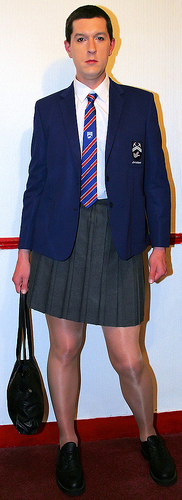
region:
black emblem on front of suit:
[130, 139, 144, 160]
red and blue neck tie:
[81, 94, 98, 206]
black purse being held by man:
[3, 284, 49, 434]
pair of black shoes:
[51, 430, 179, 492]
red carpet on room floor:
[88, 422, 138, 499]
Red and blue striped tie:
[82, 94, 96, 207]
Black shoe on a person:
[142, 433, 174, 484]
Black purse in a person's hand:
[5, 301, 48, 435]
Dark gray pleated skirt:
[24, 198, 145, 325]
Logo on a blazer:
[129, 141, 143, 165]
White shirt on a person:
[72, 74, 107, 198]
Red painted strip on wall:
[0, 236, 18, 246]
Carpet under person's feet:
[3, 434, 178, 497]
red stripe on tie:
[86, 94, 94, 99]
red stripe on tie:
[83, 115, 96, 132]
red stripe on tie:
[81, 137, 95, 158]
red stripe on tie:
[81, 148, 96, 167]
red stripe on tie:
[80, 160, 97, 178]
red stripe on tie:
[81, 172, 96, 188]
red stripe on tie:
[78, 182, 96, 202]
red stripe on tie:
[85, 194, 96, 208]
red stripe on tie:
[86, 101, 91, 108]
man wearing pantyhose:
[10, 9, 172, 494]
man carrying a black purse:
[6, 5, 180, 488]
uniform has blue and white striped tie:
[17, 61, 171, 313]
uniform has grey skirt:
[17, 178, 180, 345]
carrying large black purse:
[0, 289, 79, 441]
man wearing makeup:
[45, 3, 141, 83]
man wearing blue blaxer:
[6, 56, 171, 284]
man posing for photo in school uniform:
[8, 8, 179, 474]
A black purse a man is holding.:
[7, 284, 44, 434]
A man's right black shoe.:
[57, 436, 85, 495]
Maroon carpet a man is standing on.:
[0, 433, 181, 498]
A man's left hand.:
[148, 247, 167, 284]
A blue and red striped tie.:
[78, 92, 97, 207]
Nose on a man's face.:
[86, 37, 95, 54]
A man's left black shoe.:
[138, 431, 177, 485]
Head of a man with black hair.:
[62, 5, 115, 78]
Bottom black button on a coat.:
[110, 201, 113, 208]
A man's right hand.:
[11, 259, 28, 293]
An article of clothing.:
[20, 185, 156, 339]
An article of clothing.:
[65, 72, 118, 223]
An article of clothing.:
[85, 91, 101, 216]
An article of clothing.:
[103, 307, 162, 472]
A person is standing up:
[30, 10, 176, 440]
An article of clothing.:
[45, 439, 92, 494]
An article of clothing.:
[21, 264, 54, 440]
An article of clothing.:
[38, 196, 142, 333]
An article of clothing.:
[86, 82, 126, 209]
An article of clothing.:
[68, 66, 130, 214]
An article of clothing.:
[31, 70, 178, 234]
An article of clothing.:
[44, 24, 173, 351]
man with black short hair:
[62, 4, 114, 81]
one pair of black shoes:
[55, 431, 178, 495]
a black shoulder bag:
[5, 289, 51, 435]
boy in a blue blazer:
[16, 5, 174, 261]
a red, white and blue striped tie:
[80, 91, 97, 209]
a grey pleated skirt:
[23, 196, 144, 327]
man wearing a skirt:
[18, 4, 173, 327]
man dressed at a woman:
[11, 4, 174, 495]